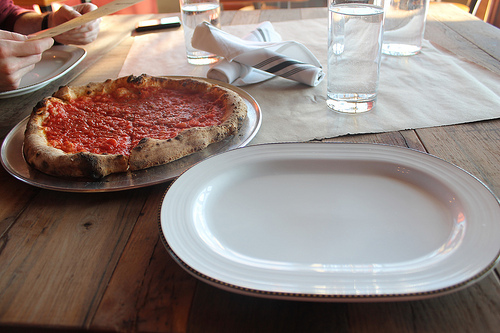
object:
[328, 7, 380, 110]
water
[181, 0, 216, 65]
glass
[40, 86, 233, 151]
sauce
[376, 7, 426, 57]
water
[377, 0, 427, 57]
glass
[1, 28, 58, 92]
hand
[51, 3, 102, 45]
hand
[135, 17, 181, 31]
cell phone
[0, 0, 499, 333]
table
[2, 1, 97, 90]
person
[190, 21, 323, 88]
napkin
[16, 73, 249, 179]
pizza crust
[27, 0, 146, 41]
menu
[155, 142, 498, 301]
plate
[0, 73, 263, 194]
plate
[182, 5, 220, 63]
glass water